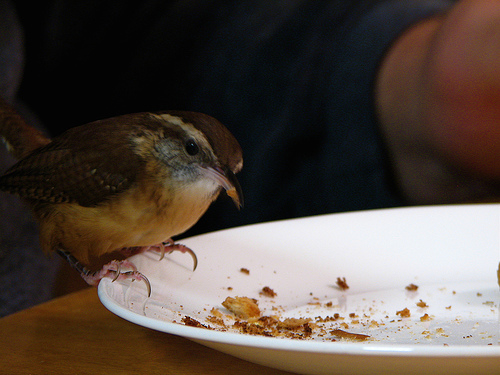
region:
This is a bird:
[7, 91, 271, 301]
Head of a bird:
[147, 105, 263, 205]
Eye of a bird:
[176, 128, 212, 161]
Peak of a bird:
[208, 163, 255, 220]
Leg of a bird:
[30, 240, 167, 309]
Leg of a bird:
[127, 218, 242, 283]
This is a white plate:
[70, 203, 497, 367]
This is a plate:
[82, 203, 494, 370]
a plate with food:
[81, 191, 498, 339]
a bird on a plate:
[89, 56, 308, 303]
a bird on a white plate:
[41, 47, 403, 371]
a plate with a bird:
[57, 113, 474, 373]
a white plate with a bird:
[44, 72, 365, 364]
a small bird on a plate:
[55, 32, 297, 282]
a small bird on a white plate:
[19, 56, 408, 374]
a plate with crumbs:
[178, 140, 495, 350]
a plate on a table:
[176, 186, 493, 369]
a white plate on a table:
[36, 168, 494, 362]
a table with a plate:
[35, 150, 467, 354]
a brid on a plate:
[6, 104, 248, 294]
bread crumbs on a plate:
[163, 268, 385, 338]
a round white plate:
[94, 203, 499, 355]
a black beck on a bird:
[219, 173, 246, 215]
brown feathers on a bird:
[13, 116, 142, 231]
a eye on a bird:
[180, 135, 205, 173]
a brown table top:
[4, 286, 220, 367]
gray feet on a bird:
[58, 244, 198, 294]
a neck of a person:
[375, 0, 499, 171]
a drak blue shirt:
[32, 16, 439, 111]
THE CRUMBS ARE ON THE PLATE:
[150, 265, 480, 347]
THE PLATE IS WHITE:
[85, 201, 495, 372]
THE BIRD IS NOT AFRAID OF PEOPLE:
[0, 102, 251, 299]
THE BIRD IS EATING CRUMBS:
[0, 60, 260, 296]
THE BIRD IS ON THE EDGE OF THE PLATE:
[0, 50, 276, 310]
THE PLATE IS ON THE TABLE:
[80, 187, 498, 369]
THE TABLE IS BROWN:
[2, 282, 357, 372]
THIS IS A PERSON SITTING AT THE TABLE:
[0, 0, 496, 325]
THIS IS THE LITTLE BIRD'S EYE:
[180, 135, 198, 171]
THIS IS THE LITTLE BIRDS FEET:
[196, 158, 246, 225]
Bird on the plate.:
[2, 93, 247, 299]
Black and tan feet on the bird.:
[53, 235, 201, 297]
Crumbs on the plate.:
[182, 261, 494, 339]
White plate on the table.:
[96, 202, 497, 373]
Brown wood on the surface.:
[2, 277, 284, 373]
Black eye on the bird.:
[180, 132, 203, 158]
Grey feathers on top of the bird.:
[10, 108, 245, 218]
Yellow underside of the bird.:
[11, 106, 226, 251]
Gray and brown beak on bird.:
[165, 115, 246, 215]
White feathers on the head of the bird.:
[132, 105, 245, 201]